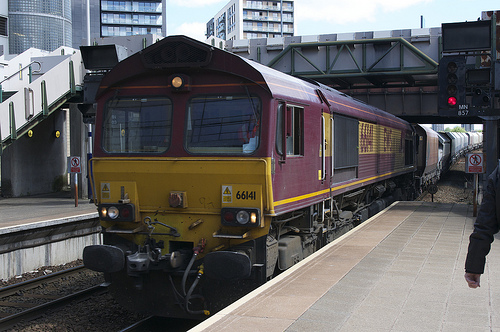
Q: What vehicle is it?
A: Train.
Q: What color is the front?
A: Yellow.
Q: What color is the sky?
A: Blue.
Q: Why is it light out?
A: Sunshine.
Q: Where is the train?
A: Tracks.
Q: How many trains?
A: One.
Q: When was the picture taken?
A: Daytime.